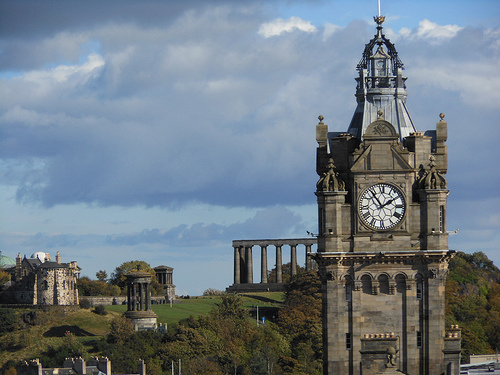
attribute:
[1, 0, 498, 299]
sky — blue, cloudy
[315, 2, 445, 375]
tower — ornamental, decorative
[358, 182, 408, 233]
clock — 1:55, roman, 2, circular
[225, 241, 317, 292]
building — historic, stone, gray, grey, structure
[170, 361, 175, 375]
chimney — rowed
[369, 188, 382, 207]
hand — black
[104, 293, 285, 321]
field — green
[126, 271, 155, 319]
pillars — round, six, four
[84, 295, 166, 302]
wall — brick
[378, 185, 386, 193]
number — roman